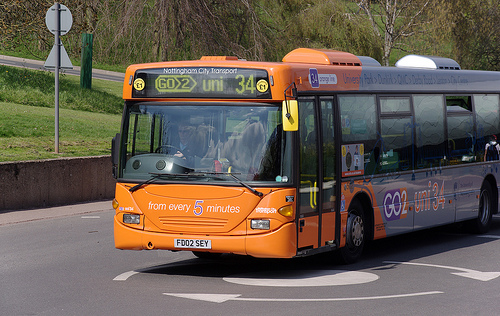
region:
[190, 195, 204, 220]
the number 5 on the front of the bus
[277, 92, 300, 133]
the yellow mirror on the bus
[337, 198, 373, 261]
the front left wheel of the bus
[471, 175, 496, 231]
the back left wheel of the bus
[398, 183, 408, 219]
the number 2 on the side of the bus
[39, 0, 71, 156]
a traffic sign on the side of the road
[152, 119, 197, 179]
the driver of the bus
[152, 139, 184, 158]
the steering wheel of the bus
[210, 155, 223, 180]
a red object in the front of the bus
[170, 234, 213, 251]
the front license plate of the bus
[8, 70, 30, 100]
this is the grass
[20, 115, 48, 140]
the grass is green in color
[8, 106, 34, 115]
the grass is short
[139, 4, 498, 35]
these are some trees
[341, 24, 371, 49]
the leaves are green in color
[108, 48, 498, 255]
this is a bus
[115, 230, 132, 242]
the bus is orange in color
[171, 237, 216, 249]
this is a number plate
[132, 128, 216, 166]
this is a driver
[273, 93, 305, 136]
this is a sidemirror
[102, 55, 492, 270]
Multi colored bus on the road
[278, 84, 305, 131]
Black color steel with yellow color side mirror of the bus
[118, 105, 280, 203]
Front glass with wipers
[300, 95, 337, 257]
Main door of the bus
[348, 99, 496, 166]
Glass windows of the bus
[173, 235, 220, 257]
White and black color number board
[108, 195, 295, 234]
Head lights with side indicators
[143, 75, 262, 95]
Yellow color led place disply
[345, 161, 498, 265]
Wheels of the bus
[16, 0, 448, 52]
Lot of trees near the road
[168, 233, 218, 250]
license plate of the bus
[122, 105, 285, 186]
front window of the bus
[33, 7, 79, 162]
a street sign on the side of the road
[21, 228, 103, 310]
black asphalt of the road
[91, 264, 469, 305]
white directional figures on the road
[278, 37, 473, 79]
silver and orange air vents on the top of the bus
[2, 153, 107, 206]
concrete retaining wall next to the road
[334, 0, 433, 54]
dead tree behind the bus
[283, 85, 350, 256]
glass doors of the bus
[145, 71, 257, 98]
yellow route lettering on the front of the bus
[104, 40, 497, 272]
an orange bus travelling over a roundabout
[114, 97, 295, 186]
front windshield of a bus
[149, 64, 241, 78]
bus belongs to Nottingham City transport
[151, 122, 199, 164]
bus driver at the wheel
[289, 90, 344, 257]
bus doors are closed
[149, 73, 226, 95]
destination on front of a bus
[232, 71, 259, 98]
bus is number 34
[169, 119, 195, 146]
bus driver wears sunglasses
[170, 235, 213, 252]
black and white license plate on a bus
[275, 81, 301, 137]
side mirror on a bus